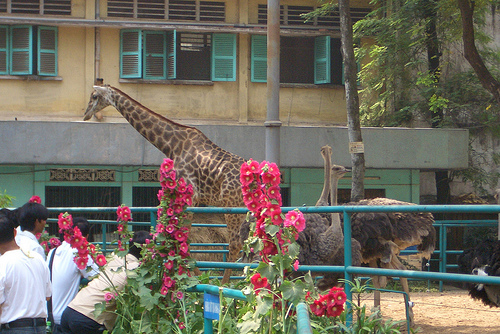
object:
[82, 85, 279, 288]
giraffe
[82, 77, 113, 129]
head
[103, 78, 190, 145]
mane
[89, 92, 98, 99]
eye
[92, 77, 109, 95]
ear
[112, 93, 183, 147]
neck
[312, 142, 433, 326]
ostrich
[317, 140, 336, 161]
head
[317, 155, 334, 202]
neck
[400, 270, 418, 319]
leg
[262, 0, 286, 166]
pole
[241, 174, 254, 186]
flowers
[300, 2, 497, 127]
leaves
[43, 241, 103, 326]
shirts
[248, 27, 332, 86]
shutters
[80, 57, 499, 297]
animals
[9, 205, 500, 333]
cage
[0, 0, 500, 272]
buildings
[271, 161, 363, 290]
ostriches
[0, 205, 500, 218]
fence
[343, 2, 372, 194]
trunk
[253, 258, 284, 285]
leaves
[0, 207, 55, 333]
men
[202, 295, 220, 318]
sign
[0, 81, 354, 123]
wall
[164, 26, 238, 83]
windows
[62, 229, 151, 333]
people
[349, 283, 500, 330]
ground